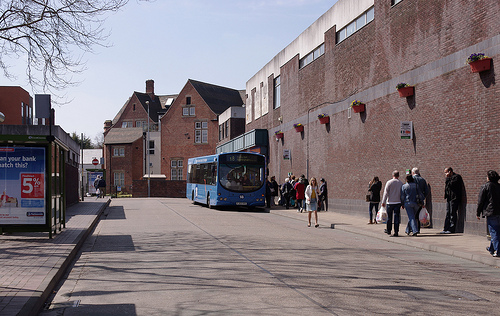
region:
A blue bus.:
[181, 147, 268, 205]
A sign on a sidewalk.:
[2, 146, 48, 228]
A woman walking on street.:
[296, 180, 326, 227]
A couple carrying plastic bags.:
[378, 171, 433, 236]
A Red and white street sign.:
[90, 155, 102, 165]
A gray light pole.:
[140, 97, 160, 197]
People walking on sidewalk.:
[266, 160, 498, 239]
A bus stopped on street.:
[180, 150, 267, 207]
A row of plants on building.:
[265, 64, 499, 145]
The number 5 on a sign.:
[19, 173, 33, 195]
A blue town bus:
[183, 154, 290, 214]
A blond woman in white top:
[304, 177, 322, 224]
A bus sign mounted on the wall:
[390, 115, 422, 137]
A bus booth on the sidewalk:
[10, 124, 77, 234]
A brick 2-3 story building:
[92, 73, 192, 207]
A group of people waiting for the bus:
[268, 172, 303, 202]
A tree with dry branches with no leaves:
[13, 7, 115, 74]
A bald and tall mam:
[435, 155, 469, 240]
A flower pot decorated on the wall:
[465, 49, 492, 74]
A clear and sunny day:
[126, 14, 257, 64]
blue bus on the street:
[175, 147, 274, 209]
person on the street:
[301, 173, 322, 233]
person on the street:
[359, 172, 389, 234]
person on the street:
[380, 167, 406, 247]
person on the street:
[399, 170, 425, 240]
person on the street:
[409, 162, 429, 211]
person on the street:
[440, 164, 464, 234]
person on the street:
[472, 168, 498, 261]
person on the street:
[318, 173, 332, 210]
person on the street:
[291, 172, 309, 215]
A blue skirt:
[304, 196, 320, 212]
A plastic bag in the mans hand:
[372, 202, 392, 223]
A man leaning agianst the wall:
[433, 162, 465, 237]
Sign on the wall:
[396, 115, 416, 144]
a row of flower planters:
[284, 91, 449, 135]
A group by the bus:
[269, 172, 308, 209]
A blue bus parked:
[183, 155, 266, 210]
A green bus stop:
[4, 130, 69, 233]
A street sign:
[91, 152, 101, 170]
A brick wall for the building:
[329, 137, 360, 214]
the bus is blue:
[121, 86, 343, 263]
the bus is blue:
[184, 130, 275, 308]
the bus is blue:
[148, 74, 261, 246]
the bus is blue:
[204, 108, 316, 313]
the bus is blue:
[157, 93, 271, 283]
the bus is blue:
[199, 48, 289, 298]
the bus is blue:
[144, 99, 306, 314]